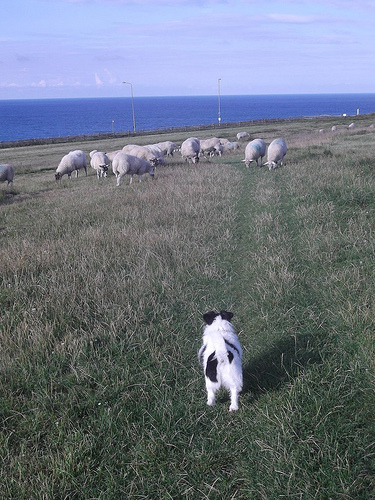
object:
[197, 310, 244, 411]
dog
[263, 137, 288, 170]
sheep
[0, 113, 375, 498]
field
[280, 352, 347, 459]
grass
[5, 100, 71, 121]
water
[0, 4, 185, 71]
sky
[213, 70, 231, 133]
light